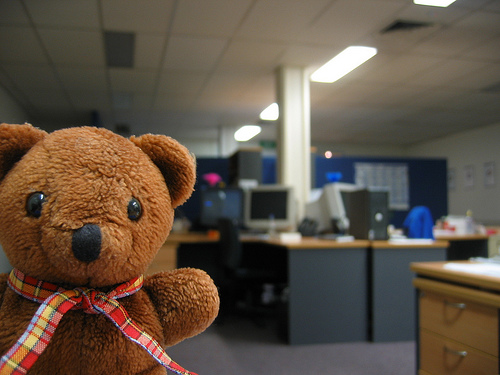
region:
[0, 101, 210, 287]
head of a teddy bear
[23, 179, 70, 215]
eye of a teddy bear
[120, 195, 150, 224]
eye of a teddy bear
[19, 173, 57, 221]
an eye of a teddy bear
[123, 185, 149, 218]
an eye of a teddy bear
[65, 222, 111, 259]
nose of a teddy bear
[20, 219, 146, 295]
mouth of a teddy bear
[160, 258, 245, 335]
arm of a teddy bear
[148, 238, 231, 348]
an arm of a teddy bear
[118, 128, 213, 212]
an ear of a teddy bear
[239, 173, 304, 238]
A monitor on the desk.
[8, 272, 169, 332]
The teddy bear has scarf around neck.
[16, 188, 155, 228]
The eyes on the bear is black.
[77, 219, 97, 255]
The nose on the bear is black.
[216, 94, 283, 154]
Lights on the ceiling are turned on.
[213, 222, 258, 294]
A black chair by the desk.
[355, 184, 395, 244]
Computer tower on top of the desk.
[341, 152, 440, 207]
The cubicle is blue.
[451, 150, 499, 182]
Papers posted on the wall.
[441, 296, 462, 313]
The handle of the drawer.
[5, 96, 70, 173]
ear of a teddy bear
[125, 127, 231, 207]
ear of a teddy bear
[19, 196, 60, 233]
eye of a teddy bear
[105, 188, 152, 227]
eye of a teddy bear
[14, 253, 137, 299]
mouth of a teddy bear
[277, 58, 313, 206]
a white pole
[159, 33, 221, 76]
a white ceiling tile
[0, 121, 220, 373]
part of a brown bear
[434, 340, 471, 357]
a gray drawer handle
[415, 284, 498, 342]
a brown drawer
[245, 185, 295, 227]
a computer monitor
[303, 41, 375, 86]
a ceiling light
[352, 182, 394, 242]
a black computer cpu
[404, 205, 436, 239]
a blue jacket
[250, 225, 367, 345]
part of a brown and black office desk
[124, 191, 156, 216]
eye of a teddy bear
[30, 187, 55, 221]
an eye of a teddy bear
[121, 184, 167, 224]
an eye of a teddy bear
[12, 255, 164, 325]
collar of a teddy bear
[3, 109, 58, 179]
an ear of a teddy bear